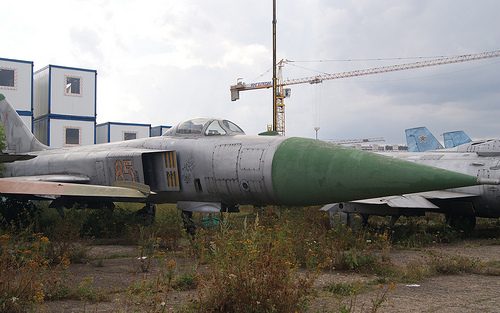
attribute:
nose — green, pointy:
[272, 133, 499, 209]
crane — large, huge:
[230, 0, 500, 134]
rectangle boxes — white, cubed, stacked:
[1, 57, 176, 148]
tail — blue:
[2, 94, 52, 153]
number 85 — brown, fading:
[115, 159, 137, 183]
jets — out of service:
[324, 126, 499, 233]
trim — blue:
[49, 66, 99, 72]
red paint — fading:
[1, 180, 157, 196]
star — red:
[417, 133, 428, 145]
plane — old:
[1, 83, 499, 262]